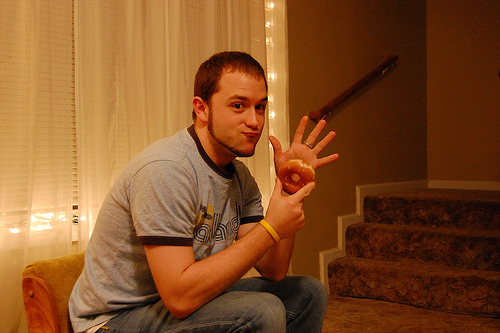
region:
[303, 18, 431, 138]
wooden hand rail attached to the wall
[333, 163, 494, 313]
set of three steps with brown carpet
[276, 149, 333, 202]
plain glazed doughnut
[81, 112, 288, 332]
blue short sleeve ringer T shirt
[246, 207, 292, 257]
yellow plastic wrist braclet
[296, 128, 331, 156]
man gold band ring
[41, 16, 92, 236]
closed white mini blinds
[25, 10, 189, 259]
white curtain shears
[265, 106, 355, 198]
man holding up five fingers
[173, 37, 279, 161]
man with brown hair and beard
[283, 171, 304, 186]
hole in the doughnut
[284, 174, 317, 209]
Index finger holding doughnut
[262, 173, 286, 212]
thumb holding doughtnut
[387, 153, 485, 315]
steps next to the man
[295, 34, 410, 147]
stairway banister above steps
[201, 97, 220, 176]
sideburn on man's face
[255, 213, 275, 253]
yellow bracelet on man's wrist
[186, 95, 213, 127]
ear on man's head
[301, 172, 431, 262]
white decorative molding on the wall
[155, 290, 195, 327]
man's right bent elbow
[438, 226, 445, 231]
part of a stair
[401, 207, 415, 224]
edge of a stair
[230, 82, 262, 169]
face of a man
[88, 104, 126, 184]
part of a curtain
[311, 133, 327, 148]
fingers of a man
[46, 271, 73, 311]
part of a chair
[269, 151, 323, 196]
A glazed donut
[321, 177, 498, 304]
Brown carpeted steps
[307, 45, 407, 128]
A small wooden railing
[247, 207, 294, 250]
A yellow bracelet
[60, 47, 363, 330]
A man holding a donut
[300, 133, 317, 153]
A silver ring on a man's hand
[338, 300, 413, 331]
A carpeted surface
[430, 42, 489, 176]
A brown painted wall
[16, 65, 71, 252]
White sheer curtains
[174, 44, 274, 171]
A man with a beard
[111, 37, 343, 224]
young white male holding donut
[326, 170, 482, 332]
three carpet covered stairs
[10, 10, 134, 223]
sheer white curtain over window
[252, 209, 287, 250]
yellow plastic bracelet on right arm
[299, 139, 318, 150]
silver ring on middle finger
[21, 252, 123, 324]
wood chair with boy sitting on it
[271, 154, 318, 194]
glazed donut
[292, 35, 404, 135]
wooden stair rail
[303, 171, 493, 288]
white molding around stairs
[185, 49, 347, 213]
boy with brown hair waving with left hand